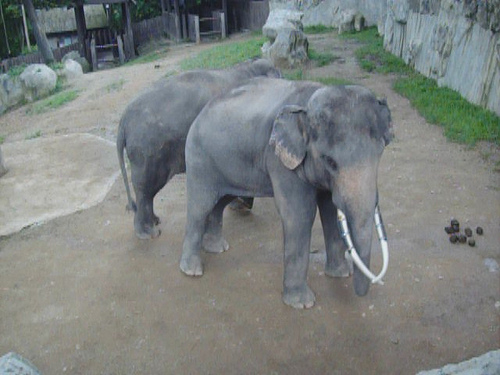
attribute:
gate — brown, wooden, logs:
[87, 28, 134, 69]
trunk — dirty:
[332, 150, 378, 297]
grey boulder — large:
[16, 63, 58, 95]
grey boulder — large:
[325, 4, 363, 29]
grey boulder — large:
[58, 50, 81, 81]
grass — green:
[437, 99, 467, 124]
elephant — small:
[116, 69, 185, 241]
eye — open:
[321, 154, 343, 175]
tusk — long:
[369, 200, 387, 285]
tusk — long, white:
[335, 202, 386, 284]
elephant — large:
[178, 85, 398, 305]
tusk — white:
[366, 199, 388, 288]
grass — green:
[1, 2, 499, 170]